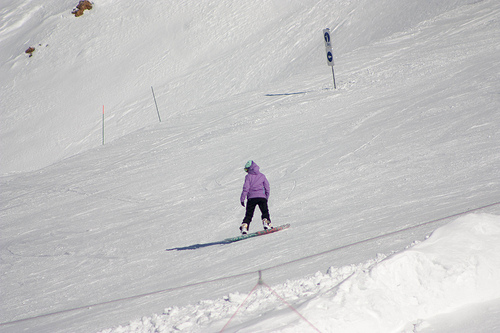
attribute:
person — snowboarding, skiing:
[230, 158, 272, 234]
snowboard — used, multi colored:
[199, 221, 292, 243]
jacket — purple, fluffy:
[244, 174, 275, 202]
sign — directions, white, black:
[321, 28, 338, 65]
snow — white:
[117, 84, 494, 323]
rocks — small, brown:
[19, 40, 54, 62]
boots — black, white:
[240, 218, 276, 232]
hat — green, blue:
[245, 158, 257, 169]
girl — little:
[245, 158, 279, 235]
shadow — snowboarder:
[166, 236, 228, 255]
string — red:
[259, 281, 288, 318]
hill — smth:
[117, 64, 496, 232]